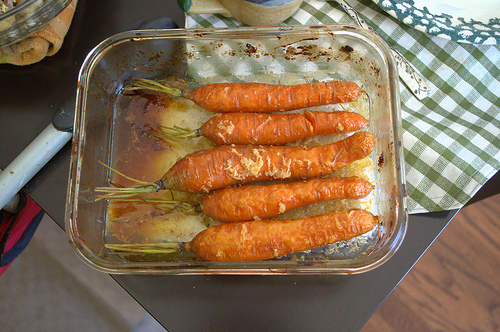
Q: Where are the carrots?
A: In the pyrex.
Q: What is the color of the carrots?
A: Orange.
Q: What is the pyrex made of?
A: Glass.